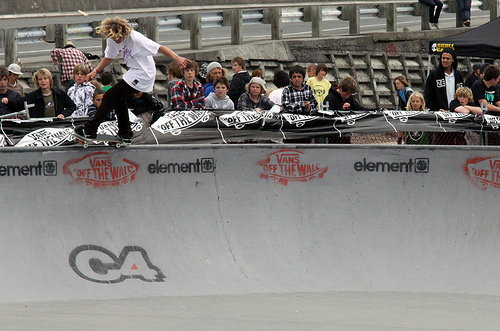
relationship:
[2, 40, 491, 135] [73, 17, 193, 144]
people watching boy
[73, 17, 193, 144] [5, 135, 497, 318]
boy doing tricks on ramp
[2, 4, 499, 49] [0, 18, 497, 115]
rail on road behind people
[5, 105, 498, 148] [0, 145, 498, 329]
banner behind ramp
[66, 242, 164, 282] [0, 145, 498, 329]
c4 name of ramp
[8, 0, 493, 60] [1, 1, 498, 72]
road in background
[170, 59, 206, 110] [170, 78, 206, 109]
boy has on plaid shirt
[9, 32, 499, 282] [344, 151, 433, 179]
skatepark has word element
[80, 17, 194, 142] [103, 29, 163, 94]
boy has a shirt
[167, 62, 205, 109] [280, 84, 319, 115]
boy has a plaid shirt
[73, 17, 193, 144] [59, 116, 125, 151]
boy riding a skateboard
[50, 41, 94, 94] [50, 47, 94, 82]
man in plaid shirt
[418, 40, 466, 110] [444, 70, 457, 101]
adult with shirt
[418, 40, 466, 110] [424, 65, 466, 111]
adult with jacket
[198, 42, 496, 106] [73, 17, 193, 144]
barrier behind boy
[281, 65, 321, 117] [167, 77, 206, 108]
boy in plaid shirt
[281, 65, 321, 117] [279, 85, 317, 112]
boy in plaid shirt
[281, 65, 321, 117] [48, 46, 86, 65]
boy in plaid shirt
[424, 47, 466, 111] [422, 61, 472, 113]
adult with coat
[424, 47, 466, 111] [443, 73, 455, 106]
adult with shirt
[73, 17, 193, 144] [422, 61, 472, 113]
boy with coat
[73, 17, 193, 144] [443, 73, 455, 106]
boy with shirt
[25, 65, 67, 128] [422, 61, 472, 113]
man with coat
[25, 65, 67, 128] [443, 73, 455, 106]
man with shirt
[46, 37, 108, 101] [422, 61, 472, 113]
man with coat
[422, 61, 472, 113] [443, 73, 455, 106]
coat with shirt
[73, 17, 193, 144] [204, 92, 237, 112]
boy in sweatshirt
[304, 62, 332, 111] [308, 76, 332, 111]
boy in shirt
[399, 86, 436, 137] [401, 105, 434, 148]
girl with shirt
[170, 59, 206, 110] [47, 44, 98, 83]
boy wears shirt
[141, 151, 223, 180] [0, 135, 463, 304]
name on ramp